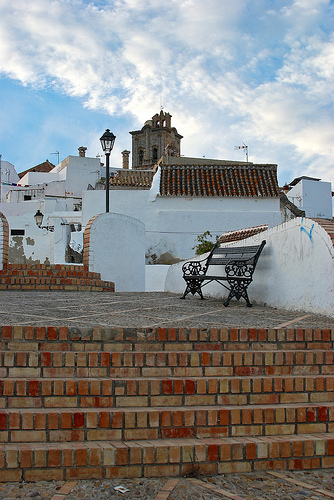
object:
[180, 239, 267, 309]
bench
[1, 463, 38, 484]
steps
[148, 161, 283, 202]
roof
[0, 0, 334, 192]
sky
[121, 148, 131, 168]
chimney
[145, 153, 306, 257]
building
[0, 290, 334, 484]
staircase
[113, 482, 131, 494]
trash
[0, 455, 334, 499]
bottom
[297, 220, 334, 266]
graffit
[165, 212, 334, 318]
wall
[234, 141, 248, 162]
antenna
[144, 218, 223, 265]
paint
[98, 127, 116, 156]
light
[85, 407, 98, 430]
bricks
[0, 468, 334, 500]
ground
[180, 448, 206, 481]
grass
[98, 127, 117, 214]
lamp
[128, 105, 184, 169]
buildings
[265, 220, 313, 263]
paint